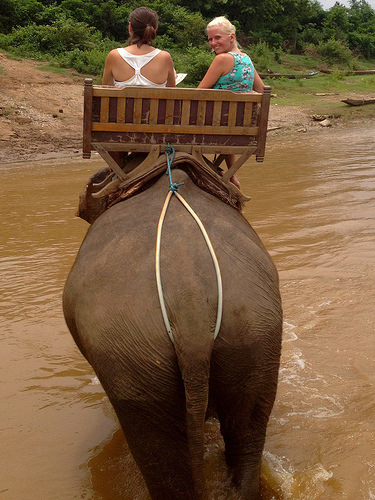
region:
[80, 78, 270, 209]
a wooden bench on top of an elephant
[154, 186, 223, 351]
a white strap securing the chair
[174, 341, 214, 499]
the tail of the elephant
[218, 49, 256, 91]
the girl is wearing a green blouse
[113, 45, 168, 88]
the girl is wearing a white blouse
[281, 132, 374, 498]
a muddy brown river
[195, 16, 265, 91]
a woman sitting down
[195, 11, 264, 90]
a blonde girl looking behind herself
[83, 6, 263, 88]
two people riding an elephant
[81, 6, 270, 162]
a bench with people on it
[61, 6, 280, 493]
an elephant carrying people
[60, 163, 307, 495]
an elephant standing in water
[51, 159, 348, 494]
elephant walking across a river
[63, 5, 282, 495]
tourists riding an animal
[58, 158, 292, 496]
a large animal traveling through water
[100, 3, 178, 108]
a woman sitting in a chair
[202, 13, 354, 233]
a woman riding an elephant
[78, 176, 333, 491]
an elephatn walking outside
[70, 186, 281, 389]
an elphant walking on the water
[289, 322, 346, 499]
a body of water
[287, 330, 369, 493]
a body of calm water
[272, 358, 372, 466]
a body of water that is murky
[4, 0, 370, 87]
some green trees in the background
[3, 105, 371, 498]
a brown river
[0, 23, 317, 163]
a dirt road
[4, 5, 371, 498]
a gray elephant in the water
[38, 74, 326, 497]
an elephant attached to a wooden bench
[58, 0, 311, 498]
two women riding an elephant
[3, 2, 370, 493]
a scene outside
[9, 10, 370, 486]
a scene at a river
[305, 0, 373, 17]
a white sky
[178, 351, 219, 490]
A gray scaly hanging elephat's tail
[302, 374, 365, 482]
Muddy brown water with some foamy spots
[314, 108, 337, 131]
Several small jagged rocks on the ground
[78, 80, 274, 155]
The rear of a wooden bench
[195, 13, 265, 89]
woman on a bench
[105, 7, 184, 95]
woman on a bench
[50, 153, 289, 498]
back of an elephant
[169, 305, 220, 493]
tail of the elephant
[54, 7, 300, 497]
people riding on an elephant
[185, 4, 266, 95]
a woman is smiling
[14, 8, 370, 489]
elephant walking in water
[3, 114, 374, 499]
a body of water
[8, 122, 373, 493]
the water is brown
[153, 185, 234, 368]
chord on the elephant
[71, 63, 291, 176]
the bench is brown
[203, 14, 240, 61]
the woman has blonde hair